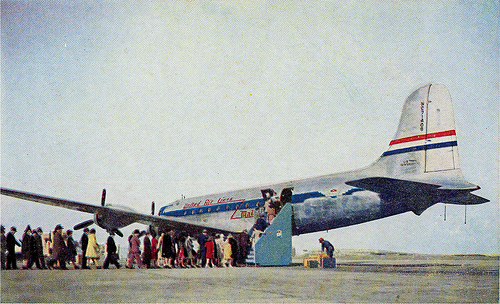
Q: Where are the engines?
A: On the wing.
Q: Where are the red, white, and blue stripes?
A: On the plane's tail.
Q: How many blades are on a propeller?
A: Three.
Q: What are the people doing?
A: Getting on the plane.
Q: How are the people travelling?
A: By airplane.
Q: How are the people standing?
A: In a row.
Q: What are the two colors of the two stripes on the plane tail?
A: Red and blue.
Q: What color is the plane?
A: White, red and blue.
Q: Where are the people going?
A: Onto the plane.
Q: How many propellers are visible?
A: Two.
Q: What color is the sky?
A: Blue.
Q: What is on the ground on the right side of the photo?
A: Luggage.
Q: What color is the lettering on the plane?
A: Red.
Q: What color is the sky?
A: Blue.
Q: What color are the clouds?
A: White.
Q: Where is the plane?
A: On pavement.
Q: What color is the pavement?
A: Gray.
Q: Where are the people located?
A: On pavement.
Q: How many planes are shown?
A: One.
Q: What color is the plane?
A: Silver.